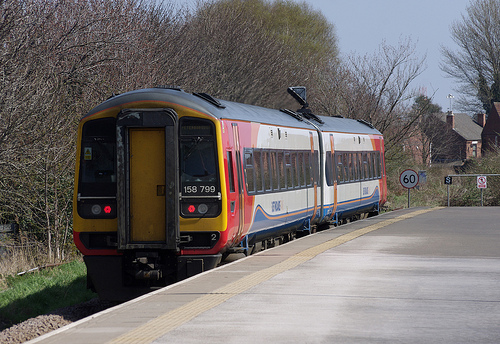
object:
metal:
[444, 174, 454, 205]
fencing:
[441, 172, 473, 206]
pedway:
[223, 207, 494, 342]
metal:
[399, 169, 421, 187]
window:
[237, 143, 259, 205]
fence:
[446, 173, 485, 207]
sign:
[476, 176, 486, 187]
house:
[393, 119, 431, 166]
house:
[476, 98, 498, 165]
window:
[333, 149, 345, 184]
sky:
[367, 1, 409, 45]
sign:
[444, 173, 457, 186]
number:
[445, 173, 455, 186]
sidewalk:
[29, 197, 499, 342]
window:
[179, 120, 217, 184]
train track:
[0, 292, 115, 332]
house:
[417, 90, 484, 163]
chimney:
[442, 109, 457, 131]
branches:
[184, 23, 256, 64]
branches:
[23, 10, 118, 89]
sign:
[398, 167, 423, 191]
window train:
[262, 153, 276, 195]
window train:
[352, 151, 364, 179]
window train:
[297, 151, 308, 188]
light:
[196, 200, 208, 215]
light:
[185, 202, 196, 214]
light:
[103, 204, 113, 214]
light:
[87, 201, 104, 216]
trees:
[0, 7, 165, 91]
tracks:
[68, 81, 396, 258]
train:
[50, 83, 393, 270]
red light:
[186, 202, 195, 214]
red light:
[102, 203, 114, 216]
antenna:
[286, 86, 313, 112]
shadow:
[0, 272, 135, 327]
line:
[226, 208, 414, 305]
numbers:
[181, 180, 217, 198]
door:
[124, 126, 172, 242]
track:
[6, 194, 436, 341]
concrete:
[56, 203, 485, 339]